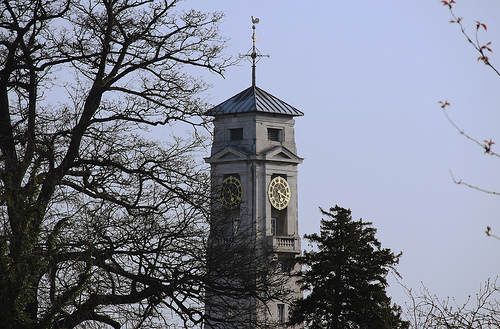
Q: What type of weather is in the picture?
A: It is clear.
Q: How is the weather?
A: It is clear.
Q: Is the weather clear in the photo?
A: Yes, it is clear.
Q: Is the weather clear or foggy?
A: It is clear.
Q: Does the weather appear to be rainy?
A: No, it is clear.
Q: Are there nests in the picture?
A: No, there are no nests.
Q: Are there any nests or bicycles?
A: No, there are no nests or bicycles.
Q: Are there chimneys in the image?
A: No, there are no chimneys.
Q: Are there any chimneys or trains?
A: No, there are no chimneys or trains.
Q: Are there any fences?
A: No, there are no fences.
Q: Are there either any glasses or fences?
A: No, there are no fences or glasses.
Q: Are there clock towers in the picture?
A: Yes, there is a clock tower.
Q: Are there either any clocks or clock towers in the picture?
A: Yes, there is a clock tower.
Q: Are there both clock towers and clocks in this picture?
A: Yes, there are both a clock tower and a clock.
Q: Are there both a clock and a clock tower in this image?
A: Yes, there are both a clock tower and a clock.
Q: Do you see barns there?
A: No, there are no barns.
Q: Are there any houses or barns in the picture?
A: No, there are no barns or houses.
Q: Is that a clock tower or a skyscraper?
A: That is a clock tower.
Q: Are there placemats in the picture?
A: No, there are no placemats.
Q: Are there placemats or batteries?
A: No, there are no placemats or batteries.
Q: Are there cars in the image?
A: No, there are no cars.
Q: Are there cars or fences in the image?
A: No, there are no cars or fences.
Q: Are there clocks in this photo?
A: Yes, there is a clock.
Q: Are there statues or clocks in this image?
A: Yes, there is a clock.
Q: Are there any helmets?
A: No, there are no helmets.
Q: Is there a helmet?
A: No, there are no helmets.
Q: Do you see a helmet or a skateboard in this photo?
A: No, there are no helmets or skateboards.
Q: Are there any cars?
A: No, there are no cars.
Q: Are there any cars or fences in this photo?
A: No, there are no cars or fences.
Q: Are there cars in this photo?
A: No, there are no cars.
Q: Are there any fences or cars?
A: No, there are no cars or fences.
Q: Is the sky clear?
A: Yes, the sky is clear.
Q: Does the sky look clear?
A: Yes, the sky is clear.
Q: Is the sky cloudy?
A: No, the sky is clear.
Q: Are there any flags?
A: No, there are no flags.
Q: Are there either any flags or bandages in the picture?
A: No, there are no flags or bandages.